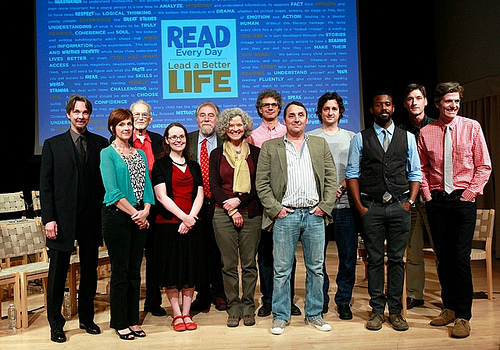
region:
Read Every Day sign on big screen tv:
[33, 0, 364, 155]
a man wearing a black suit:
[38, 96, 110, 341]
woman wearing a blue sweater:
[100, 108, 155, 340]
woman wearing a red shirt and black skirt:
[150, 122, 203, 331]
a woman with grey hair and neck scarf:
[208, 107, 260, 326]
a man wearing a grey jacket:
[255, 102, 339, 334]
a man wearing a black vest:
[348, 90, 421, 330]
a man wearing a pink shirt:
[417, 82, 490, 337]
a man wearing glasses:
[250, 90, 300, 316]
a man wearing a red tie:
[185, 101, 220, 311]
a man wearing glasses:
[129, 98, 152, 127]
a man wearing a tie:
[440, 117, 467, 208]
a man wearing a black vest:
[363, 130, 418, 208]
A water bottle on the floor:
[3, 299, 27, 338]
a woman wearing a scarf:
[218, 117, 259, 183]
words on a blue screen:
[263, 36, 325, 89]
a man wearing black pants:
[41, 207, 102, 328]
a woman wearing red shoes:
[169, 298, 206, 334]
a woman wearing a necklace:
[172, 147, 194, 172]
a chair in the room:
[7, 210, 48, 327]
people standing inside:
[32, 22, 479, 289]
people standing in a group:
[29, 28, 480, 280]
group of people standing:
[30, 32, 492, 329]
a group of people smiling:
[37, 41, 497, 286]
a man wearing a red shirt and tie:
[407, 59, 499, 240]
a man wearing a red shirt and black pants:
[444, 101, 499, 309]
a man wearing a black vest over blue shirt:
[346, 59, 437, 299]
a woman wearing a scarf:
[190, 76, 302, 326]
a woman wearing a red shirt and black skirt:
[137, 98, 216, 306]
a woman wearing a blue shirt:
[67, 108, 165, 318]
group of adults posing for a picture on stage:
[28, 76, 492, 348]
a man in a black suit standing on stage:
[38, 92, 106, 349]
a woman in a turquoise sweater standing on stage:
[98, 106, 153, 338]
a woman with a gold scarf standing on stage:
[214, 103, 261, 333]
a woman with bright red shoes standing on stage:
[151, 118, 206, 334]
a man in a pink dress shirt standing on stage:
[415, 78, 487, 343]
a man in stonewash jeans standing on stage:
[254, 108, 344, 349]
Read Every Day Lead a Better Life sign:
[156, 18, 248, 105]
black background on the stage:
[371, 8, 473, 72]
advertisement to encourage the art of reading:
[30, 0, 371, 156]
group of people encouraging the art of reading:
[35, 80, 493, 345]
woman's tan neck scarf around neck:
[220, 139, 253, 195]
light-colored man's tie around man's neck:
[441, 120, 458, 197]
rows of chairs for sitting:
[0, 185, 119, 335]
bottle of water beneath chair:
[5, 302, 18, 333]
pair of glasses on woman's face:
[165, 130, 186, 140]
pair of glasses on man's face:
[257, 100, 278, 111]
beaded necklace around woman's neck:
[109, 140, 136, 161]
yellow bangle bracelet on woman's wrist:
[225, 207, 240, 218]